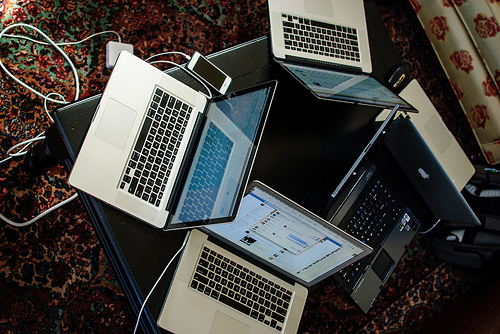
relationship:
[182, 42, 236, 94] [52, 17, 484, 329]
phone on table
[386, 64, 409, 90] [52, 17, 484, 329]
computer mouse on table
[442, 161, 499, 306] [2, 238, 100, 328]
black backpack on ground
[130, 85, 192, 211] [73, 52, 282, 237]
keys on laptop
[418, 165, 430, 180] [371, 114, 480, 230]
logo on back of screen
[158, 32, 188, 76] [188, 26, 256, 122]
plug in phone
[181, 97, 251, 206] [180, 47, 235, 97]
screen of phone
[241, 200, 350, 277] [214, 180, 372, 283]
facebook open on screen